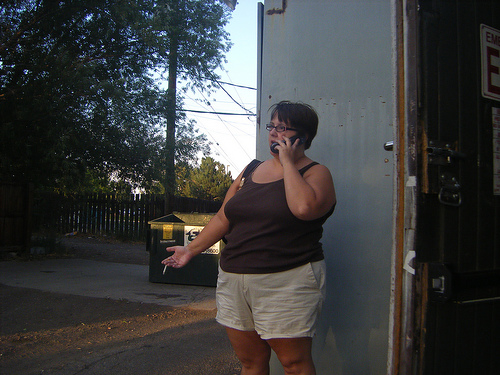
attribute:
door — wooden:
[388, 4, 427, 374]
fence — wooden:
[42, 189, 172, 241]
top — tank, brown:
[215, 154, 326, 274]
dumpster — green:
[141, 210, 223, 286]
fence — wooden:
[57, 183, 197, 241]